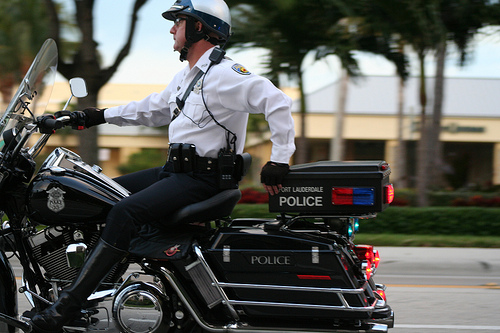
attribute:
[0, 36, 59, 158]
windshield — clear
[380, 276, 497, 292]
line — yellow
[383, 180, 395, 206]
tail light — on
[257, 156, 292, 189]
glove — black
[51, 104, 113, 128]
glove — black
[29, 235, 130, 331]
boot — on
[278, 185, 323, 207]
letters — white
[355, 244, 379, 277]
light — on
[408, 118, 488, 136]
sign — green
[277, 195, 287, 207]
letter — white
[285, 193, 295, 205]
letter — white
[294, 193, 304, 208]
letter — white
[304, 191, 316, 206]
letter — white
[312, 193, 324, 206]
letter — white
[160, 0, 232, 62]
helmet — on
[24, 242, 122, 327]
boot — black, shiny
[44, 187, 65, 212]
logo — white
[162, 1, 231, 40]
helmet — gray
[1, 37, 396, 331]
motorcycle — on the, has, on, black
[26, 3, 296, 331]
man — wears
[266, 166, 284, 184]
glove — on, worn on